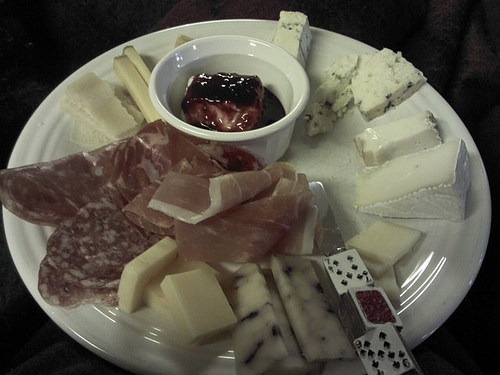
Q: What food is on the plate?
A: Meat and cheese.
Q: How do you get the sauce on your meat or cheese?
A: Dip it.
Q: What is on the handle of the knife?
A: Playing cards.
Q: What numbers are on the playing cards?
A: 7 and 9.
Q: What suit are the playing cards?
A: Spades.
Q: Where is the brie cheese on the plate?
A: To the right of the knife.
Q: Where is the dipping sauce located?
A: Inside of white ceramic bowl.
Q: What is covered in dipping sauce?
A: Cheese slice.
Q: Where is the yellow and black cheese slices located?
A: To the left of the knife playing card handle.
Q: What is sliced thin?
A: Slices of meat.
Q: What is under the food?
A: A plate.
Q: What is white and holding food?
A: A plate.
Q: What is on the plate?
A: A bowl.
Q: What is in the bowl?
A: Sauce.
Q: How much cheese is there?
A: A few slices.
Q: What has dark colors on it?
A: The cheese.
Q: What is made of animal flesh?
A: Meat.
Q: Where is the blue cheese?
A: Upper right of plate.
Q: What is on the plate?
A: Food.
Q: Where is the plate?
A: On a table.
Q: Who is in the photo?
A: No one.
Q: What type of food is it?
A: Cheese and meat.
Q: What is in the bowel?
A: Sauce.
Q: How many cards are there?
A: Three.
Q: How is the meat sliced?
A: Thin.